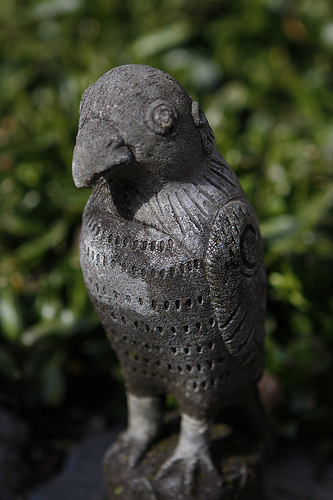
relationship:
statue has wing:
[68, 65, 269, 480] [207, 200, 267, 369]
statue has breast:
[68, 65, 269, 480] [82, 217, 233, 417]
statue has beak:
[68, 65, 269, 480] [72, 124, 130, 192]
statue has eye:
[68, 65, 269, 480] [147, 101, 176, 133]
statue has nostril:
[68, 65, 269, 480] [91, 170, 116, 182]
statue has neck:
[68, 65, 269, 480] [172, 164, 215, 177]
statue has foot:
[68, 65, 269, 480] [163, 413, 227, 495]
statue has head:
[68, 65, 269, 480] [79, 64, 206, 178]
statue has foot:
[68, 65, 269, 480] [101, 399, 159, 468]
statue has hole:
[68, 65, 269, 480] [192, 316, 203, 331]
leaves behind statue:
[4, 13, 333, 455] [68, 65, 269, 480]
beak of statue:
[72, 124, 130, 192] [68, 65, 269, 480]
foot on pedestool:
[163, 413, 227, 495] [101, 425, 264, 499]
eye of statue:
[147, 101, 176, 133] [68, 65, 269, 480]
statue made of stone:
[68, 65, 269, 480] [106, 74, 146, 119]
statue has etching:
[68, 65, 269, 480] [212, 231, 263, 339]